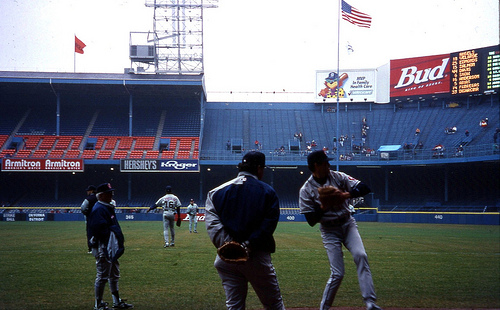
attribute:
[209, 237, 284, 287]
glove — brown, leather, baseball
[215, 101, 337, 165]
seats — blue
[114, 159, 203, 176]
logo — blue and white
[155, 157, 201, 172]
kroger sign — advertisement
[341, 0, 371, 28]
flag — red, white, blue, American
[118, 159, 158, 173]
banner — Hershey's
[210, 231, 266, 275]
glove — for baseball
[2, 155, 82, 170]
logo — red and white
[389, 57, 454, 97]
logo — red and white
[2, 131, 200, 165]
seats — red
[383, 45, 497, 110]
sign — red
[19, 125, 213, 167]
seats — orange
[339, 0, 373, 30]
flag — U.S.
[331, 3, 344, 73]
pole — tall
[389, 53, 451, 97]
billboard — large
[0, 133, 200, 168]
deck — upper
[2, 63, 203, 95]
awning — black